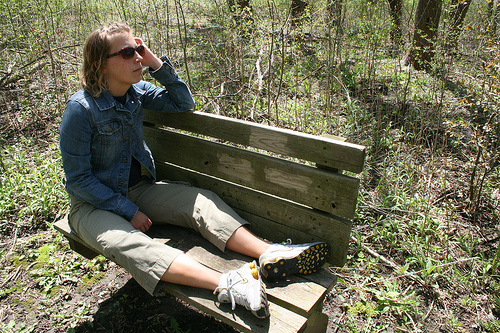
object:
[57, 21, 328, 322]
person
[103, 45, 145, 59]
sunglasses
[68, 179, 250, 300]
pants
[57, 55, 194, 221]
jacket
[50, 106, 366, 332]
bench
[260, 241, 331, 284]
shoe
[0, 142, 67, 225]
brush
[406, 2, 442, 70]
tree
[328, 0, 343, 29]
trunk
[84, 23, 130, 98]
hair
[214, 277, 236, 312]
shoelaces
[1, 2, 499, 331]
ground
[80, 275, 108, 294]
dirt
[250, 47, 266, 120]
branches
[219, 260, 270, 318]
foot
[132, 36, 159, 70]
hand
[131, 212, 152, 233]
hand